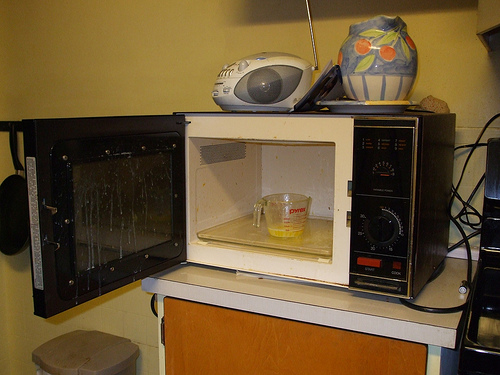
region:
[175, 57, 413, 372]
microwave is black and white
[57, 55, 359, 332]
microwave is black and white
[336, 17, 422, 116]
porcelain jar and plate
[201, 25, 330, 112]
radio on top of the oven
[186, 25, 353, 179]
radio on top of the oven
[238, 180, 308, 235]
pyrex inside of microwave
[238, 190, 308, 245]
measuring cup with handle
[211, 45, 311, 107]
radio on top of microwave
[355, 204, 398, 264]
knob on black microwave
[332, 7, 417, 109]
ceramic pitcher on microwave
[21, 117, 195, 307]
dirty black microwave door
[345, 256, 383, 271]
red button on microwave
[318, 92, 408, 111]
plate on bottom of pitcher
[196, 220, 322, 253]
plate at bottom of microwave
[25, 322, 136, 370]
stool on floor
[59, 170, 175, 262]
Explosion on door of microwave.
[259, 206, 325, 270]
Yellow liquid in measuring cup.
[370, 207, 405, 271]
black knob on microwave.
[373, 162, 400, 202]
Black knob on microwave.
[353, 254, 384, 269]
Red button on microwave.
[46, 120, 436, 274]
Microwave is black in color.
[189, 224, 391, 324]
Microwave is sitting on white counter top.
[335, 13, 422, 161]
Ceramic pitcher on top of microwave.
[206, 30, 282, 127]
White radio on top of microwave.